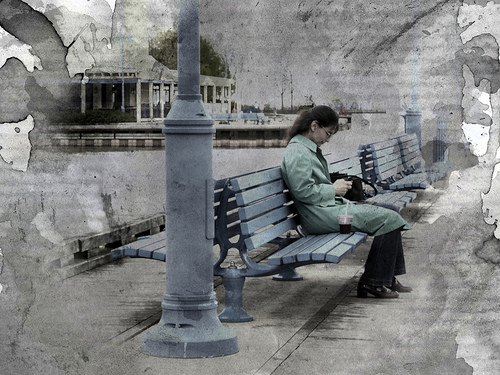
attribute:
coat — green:
[279, 134, 413, 236]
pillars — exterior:
[49, 74, 166, 111]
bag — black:
[328, 171, 378, 203]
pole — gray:
[146, 5, 241, 373]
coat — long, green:
[284, 148, 366, 239]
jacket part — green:
[288, 149, 322, 176]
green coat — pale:
[281, 140, 408, 235]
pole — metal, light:
[139, 56, 243, 346]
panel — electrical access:
[199, 171, 221, 263]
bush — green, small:
[77, 102, 138, 128]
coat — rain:
[275, 129, 410, 249]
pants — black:
[353, 198, 436, 315]